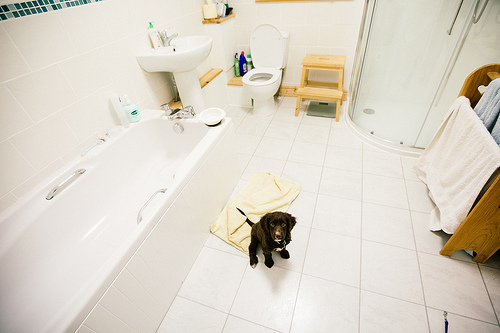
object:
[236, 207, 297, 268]
puppy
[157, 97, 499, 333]
floor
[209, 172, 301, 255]
towel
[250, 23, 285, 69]
toilet lid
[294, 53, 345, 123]
step stool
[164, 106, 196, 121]
faucet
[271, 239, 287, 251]
puppy's chest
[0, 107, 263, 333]
bathtub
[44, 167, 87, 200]
handle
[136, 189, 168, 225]
handle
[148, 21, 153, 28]
lid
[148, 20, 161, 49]
hand soap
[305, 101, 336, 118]
scale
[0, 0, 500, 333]
bathroom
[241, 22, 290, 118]
toilet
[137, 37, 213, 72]
sink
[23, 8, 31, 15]
tiles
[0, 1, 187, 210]
wall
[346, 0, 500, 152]
shower door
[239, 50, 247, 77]
items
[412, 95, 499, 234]
towel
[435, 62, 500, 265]
rack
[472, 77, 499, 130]
towel